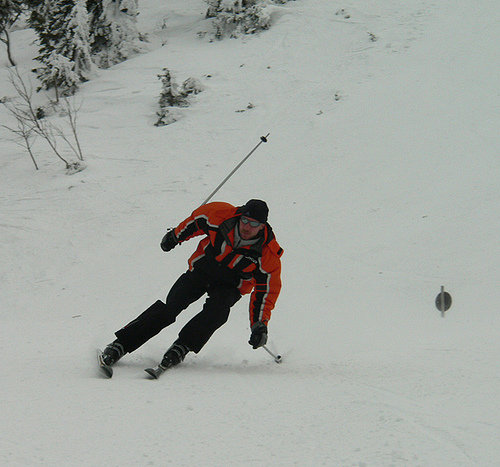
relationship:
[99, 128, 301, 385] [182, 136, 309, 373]
man holding poles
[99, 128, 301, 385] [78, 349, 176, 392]
man on skis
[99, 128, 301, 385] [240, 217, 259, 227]
man in glasses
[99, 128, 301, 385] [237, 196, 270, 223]
man in hat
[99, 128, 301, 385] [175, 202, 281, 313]
man in jacket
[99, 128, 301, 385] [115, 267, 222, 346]
man in pants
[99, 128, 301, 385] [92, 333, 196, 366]
man in boots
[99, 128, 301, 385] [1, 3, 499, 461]
man in snow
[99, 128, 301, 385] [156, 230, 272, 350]
man in gloves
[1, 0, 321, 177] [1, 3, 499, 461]
trees in snow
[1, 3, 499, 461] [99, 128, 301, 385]
snow around man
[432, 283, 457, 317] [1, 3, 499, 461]
marker in snow